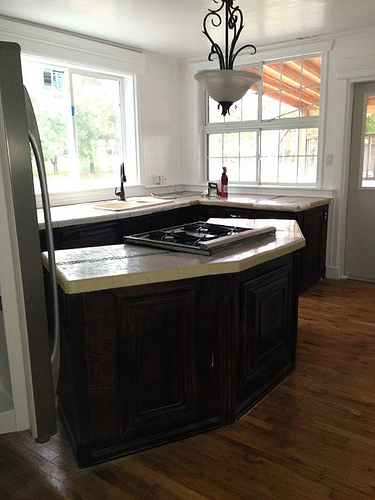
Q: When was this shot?
A: Daytime.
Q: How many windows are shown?
A: 3.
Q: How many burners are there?
A: 4.